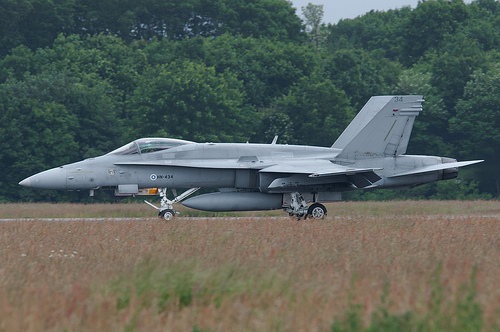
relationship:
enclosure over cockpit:
[106, 133, 190, 155] [102, 129, 195, 159]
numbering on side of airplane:
[154, 174, 175, 179] [17, 93, 486, 221]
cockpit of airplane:
[109, 136, 189, 153] [19, 93, 475, 216]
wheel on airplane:
[309, 202, 329, 223] [19, 93, 475, 216]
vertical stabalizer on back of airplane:
[334, 94, 424, 161] [17, 93, 486, 221]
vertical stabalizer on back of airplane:
[330, 95, 394, 149] [17, 93, 486, 221]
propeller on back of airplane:
[397, 153, 484, 187] [13, 84, 476, 229]